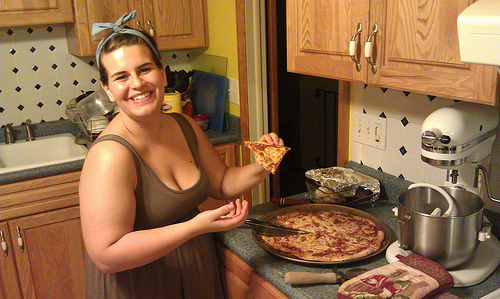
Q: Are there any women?
A: Yes, there is a woman.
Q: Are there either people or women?
A: Yes, there is a woman.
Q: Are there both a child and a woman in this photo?
A: No, there is a woman but no children.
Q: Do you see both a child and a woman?
A: No, there is a woman but no children.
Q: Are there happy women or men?
A: Yes, there is a happy woman.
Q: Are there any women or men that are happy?
A: Yes, the woman is happy.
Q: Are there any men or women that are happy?
A: Yes, the woman is happy.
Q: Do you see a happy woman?
A: Yes, there is a happy woman.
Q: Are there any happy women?
A: Yes, there is a happy woman.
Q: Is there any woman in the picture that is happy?
A: Yes, there is a woman that is happy.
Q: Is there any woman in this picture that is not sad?
A: Yes, there is a happy woman.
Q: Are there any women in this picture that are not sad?
A: Yes, there is a happy woman.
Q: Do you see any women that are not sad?
A: Yes, there is a happy woman.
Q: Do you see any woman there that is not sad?
A: Yes, there is a happy woman.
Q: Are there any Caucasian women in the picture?
A: Yes, there is a Caucasian woman.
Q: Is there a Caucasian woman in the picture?
A: Yes, there is a Caucasian woman.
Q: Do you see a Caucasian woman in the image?
A: Yes, there is a Caucasian woman.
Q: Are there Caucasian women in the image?
A: Yes, there is a Caucasian woman.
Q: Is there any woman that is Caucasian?
A: Yes, there is a woman that is caucasian.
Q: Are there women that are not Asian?
A: Yes, there is an Caucasian woman.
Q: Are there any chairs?
A: No, there are no chairs.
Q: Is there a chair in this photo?
A: No, there are no chairs.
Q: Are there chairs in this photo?
A: No, there are no chairs.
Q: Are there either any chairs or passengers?
A: No, there are no chairs or passengers.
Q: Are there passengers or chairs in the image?
A: No, there are no chairs or passengers.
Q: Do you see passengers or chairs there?
A: No, there are no chairs or passengers.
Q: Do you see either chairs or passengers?
A: No, there are no chairs or passengers.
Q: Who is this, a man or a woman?
A: This is a woman.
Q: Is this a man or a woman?
A: This is a woman.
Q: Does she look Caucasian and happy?
A: Yes, the woman is Caucasian and happy.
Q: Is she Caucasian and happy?
A: Yes, the woman is Caucasian and happy.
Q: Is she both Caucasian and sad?
A: No, the woman is Caucasian but happy.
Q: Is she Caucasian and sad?
A: No, the woman is Caucasian but happy.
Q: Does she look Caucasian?
A: Yes, the woman is caucasian.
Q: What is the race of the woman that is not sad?
A: The woman is caucasian.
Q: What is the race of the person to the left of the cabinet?
A: The woman is caucasian.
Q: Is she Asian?
A: No, the woman is caucasian.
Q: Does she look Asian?
A: No, the woman is caucasian.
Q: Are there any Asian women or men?
A: No, there is a woman but she is caucasian.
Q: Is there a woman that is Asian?
A: No, there is a woman but she is caucasian.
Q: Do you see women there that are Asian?
A: No, there is a woman but she is caucasian.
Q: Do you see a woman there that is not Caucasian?
A: No, there is a woman but she is caucasian.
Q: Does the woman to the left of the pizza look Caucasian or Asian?
A: The woman is caucasian.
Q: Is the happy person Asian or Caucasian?
A: The woman is caucasian.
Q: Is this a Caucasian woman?
A: Yes, this is a Caucasian woman.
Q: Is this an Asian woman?
A: No, this is a Caucasian woman.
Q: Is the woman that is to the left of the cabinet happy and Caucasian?
A: Yes, the woman is happy and caucasian.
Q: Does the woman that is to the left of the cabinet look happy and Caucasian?
A: Yes, the woman is happy and caucasian.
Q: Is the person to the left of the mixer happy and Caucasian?
A: Yes, the woman is happy and caucasian.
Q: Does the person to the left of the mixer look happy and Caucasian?
A: Yes, the woman is happy and caucasian.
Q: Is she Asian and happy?
A: No, the woman is happy but caucasian.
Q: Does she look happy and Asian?
A: No, the woman is happy but caucasian.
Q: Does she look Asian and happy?
A: No, the woman is happy but caucasian.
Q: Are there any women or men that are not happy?
A: No, there is a woman but she is happy.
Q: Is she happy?
A: Yes, the woman is happy.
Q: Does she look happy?
A: Yes, the woman is happy.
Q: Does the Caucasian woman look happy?
A: Yes, the woman is happy.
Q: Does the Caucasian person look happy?
A: Yes, the woman is happy.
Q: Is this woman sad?
A: No, the woman is happy.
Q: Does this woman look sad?
A: No, the woman is happy.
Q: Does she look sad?
A: No, the woman is happy.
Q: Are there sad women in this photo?
A: No, there is a woman but she is happy.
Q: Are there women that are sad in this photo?
A: No, there is a woman but she is happy.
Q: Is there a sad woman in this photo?
A: No, there is a woman but she is happy.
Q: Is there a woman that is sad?
A: No, there is a woman but she is happy.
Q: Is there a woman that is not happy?
A: No, there is a woman but she is happy.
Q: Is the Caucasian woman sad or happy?
A: The woman is happy.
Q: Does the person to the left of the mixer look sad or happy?
A: The woman is happy.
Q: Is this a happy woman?
A: Yes, this is a happy woman.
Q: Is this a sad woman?
A: No, this is a happy woman.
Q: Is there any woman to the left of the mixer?
A: Yes, there is a woman to the left of the mixer.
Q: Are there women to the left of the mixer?
A: Yes, there is a woman to the left of the mixer.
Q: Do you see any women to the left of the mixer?
A: Yes, there is a woman to the left of the mixer.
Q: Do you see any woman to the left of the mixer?
A: Yes, there is a woman to the left of the mixer.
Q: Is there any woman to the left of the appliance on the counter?
A: Yes, there is a woman to the left of the mixer.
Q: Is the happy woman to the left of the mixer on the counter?
A: Yes, the woman is to the left of the mixer.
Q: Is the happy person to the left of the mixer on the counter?
A: Yes, the woman is to the left of the mixer.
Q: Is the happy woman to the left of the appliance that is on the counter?
A: Yes, the woman is to the left of the mixer.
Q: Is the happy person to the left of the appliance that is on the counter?
A: Yes, the woman is to the left of the mixer.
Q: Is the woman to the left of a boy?
A: No, the woman is to the left of the mixer.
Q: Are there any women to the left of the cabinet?
A: Yes, there is a woman to the left of the cabinet.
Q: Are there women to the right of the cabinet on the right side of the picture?
A: No, the woman is to the left of the cabinet.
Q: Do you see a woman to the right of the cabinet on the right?
A: No, the woman is to the left of the cabinet.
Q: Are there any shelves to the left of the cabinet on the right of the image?
A: No, there is a woman to the left of the cabinet.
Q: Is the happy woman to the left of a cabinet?
A: Yes, the woman is to the left of a cabinet.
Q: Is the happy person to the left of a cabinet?
A: Yes, the woman is to the left of a cabinet.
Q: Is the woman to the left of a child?
A: No, the woman is to the left of a cabinet.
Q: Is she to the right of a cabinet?
A: No, the woman is to the left of a cabinet.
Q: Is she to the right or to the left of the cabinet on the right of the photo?
A: The woman is to the left of the cabinet.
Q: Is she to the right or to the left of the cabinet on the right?
A: The woman is to the left of the cabinet.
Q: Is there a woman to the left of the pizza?
A: Yes, there is a woman to the left of the pizza.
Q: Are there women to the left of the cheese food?
A: Yes, there is a woman to the left of the pizza.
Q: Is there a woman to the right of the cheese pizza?
A: No, the woman is to the left of the pizza.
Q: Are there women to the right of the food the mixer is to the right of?
A: No, the woman is to the left of the pizza.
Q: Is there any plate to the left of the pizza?
A: No, there is a woman to the left of the pizza.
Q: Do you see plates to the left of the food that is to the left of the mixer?
A: No, there is a woman to the left of the pizza.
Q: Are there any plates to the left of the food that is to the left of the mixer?
A: No, there is a woman to the left of the pizza.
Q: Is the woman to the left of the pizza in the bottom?
A: Yes, the woman is to the left of the pizza.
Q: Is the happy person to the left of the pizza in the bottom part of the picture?
A: Yes, the woman is to the left of the pizza.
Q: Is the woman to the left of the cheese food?
A: Yes, the woman is to the left of the pizza.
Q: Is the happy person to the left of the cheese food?
A: Yes, the woman is to the left of the pizza.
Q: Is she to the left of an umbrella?
A: No, the woman is to the left of the pizza.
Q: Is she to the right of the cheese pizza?
A: No, the woman is to the left of the pizza.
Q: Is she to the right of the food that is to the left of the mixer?
A: No, the woman is to the left of the pizza.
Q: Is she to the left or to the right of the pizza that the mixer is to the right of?
A: The woman is to the left of the pizza.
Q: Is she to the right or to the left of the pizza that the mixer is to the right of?
A: The woman is to the left of the pizza.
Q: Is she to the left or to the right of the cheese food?
A: The woman is to the left of the pizza.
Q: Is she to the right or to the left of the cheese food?
A: The woman is to the left of the pizza.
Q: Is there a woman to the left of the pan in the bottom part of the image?
A: Yes, there is a woman to the left of the pan.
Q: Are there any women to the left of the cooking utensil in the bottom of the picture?
A: Yes, there is a woman to the left of the pan.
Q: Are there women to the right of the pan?
A: No, the woman is to the left of the pan.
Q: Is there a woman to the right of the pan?
A: No, the woman is to the left of the pan.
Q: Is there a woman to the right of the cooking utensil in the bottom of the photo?
A: No, the woman is to the left of the pan.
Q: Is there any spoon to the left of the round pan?
A: No, there is a woman to the left of the pan.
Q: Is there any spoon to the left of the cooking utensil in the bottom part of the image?
A: No, there is a woman to the left of the pan.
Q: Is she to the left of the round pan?
A: Yes, the woman is to the left of the pan.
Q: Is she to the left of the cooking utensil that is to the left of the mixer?
A: Yes, the woman is to the left of the pan.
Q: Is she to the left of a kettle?
A: No, the woman is to the left of the pan.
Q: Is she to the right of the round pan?
A: No, the woman is to the left of the pan.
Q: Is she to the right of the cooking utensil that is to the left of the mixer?
A: No, the woman is to the left of the pan.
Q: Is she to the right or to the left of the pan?
A: The woman is to the left of the pan.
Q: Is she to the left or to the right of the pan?
A: The woman is to the left of the pan.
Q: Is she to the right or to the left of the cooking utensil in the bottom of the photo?
A: The woman is to the left of the pan.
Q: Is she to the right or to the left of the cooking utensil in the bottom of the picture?
A: The woman is to the left of the pan.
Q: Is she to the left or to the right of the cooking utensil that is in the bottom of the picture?
A: The woman is to the left of the pan.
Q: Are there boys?
A: No, there are no boys.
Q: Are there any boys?
A: No, there are no boys.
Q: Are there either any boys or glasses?
A: No, there are no boys or glasses.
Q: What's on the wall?
A: The outlet is on the wall.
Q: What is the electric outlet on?
A: The electric outlet is on the wall.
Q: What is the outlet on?
A: The electric outlet is on the wall.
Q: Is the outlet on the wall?
A: Yes, the outlet is on the wall.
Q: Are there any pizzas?
A: Yes, there is a pizza.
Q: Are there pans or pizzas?
A: Yes, there is a pizza.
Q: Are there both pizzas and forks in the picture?
A: No, there is a pizza but no forks.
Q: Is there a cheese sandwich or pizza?
A: Yes, there is a cheese pizza.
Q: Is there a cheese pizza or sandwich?
A: Yes, there is a cheese pizza.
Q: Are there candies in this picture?
A: No, there are no candies.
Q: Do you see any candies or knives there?
A: No, there are no candies or knives.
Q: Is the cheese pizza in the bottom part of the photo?
A: Yes, the pizza is in the bottom of the image.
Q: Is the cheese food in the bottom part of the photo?
A: Yes, the pizza is in the bottom of the image.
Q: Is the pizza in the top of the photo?
A: No, the pizza is in the bottom of the image.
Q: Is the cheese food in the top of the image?
A: No, the pizza is in the bottom of the image.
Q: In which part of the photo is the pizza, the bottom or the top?
A: The pizza is in the bottom of the image.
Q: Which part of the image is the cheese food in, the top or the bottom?
A: The pizza is in the bottom of the image.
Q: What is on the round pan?
A: The pizza is on the pan.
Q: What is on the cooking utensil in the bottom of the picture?
A: The pizza is on the pan.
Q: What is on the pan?
A: The pizza is on the pan.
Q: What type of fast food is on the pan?
A: The food is a pizza.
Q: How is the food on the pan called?
A: The food is a pizza.